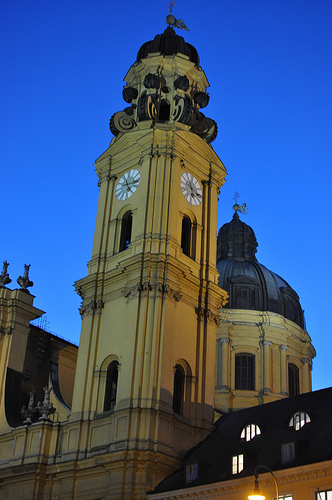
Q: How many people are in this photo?
A: 0.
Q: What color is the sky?
A: Blue.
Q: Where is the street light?
A: On the ground.